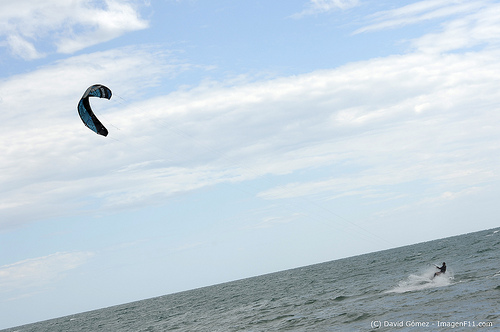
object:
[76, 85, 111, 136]
parasail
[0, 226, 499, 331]
water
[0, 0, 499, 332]
sky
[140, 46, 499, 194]
clouds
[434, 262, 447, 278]
person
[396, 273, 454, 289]
spray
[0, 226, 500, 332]
horizon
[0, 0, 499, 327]
distance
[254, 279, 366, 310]
waves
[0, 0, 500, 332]
background